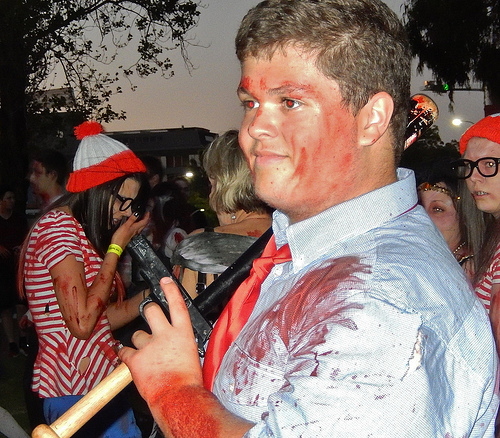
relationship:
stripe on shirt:
[38, 350, 78, 384] [19, 209, 127, 396]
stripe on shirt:
[42, 367, 66, 393] [19, 209, 127, 396]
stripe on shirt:
[40, 383, 52, 399] [19, 209, 127, 396]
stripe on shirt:
[35, 316, 61, 328] [19, 209, 127, 396]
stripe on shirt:
[24, 276, 54, 287] [19, 209, 127, 396]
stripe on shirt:
[471, 286, 493, 302] [471, 241, 497, 315]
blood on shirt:
[279, 275, 332, 321] [210, 205, 496, 435]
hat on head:
[62, 117, 143, 187] [73, 169, 135, 246]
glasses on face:
[110, 185, 138, 212] [103, 178, 137, 229]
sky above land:
[135, 74, 205, 112] [128, 123, 246, 202]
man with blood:
[111, 0, 499, 438] [293, 147, 311, 182]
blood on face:
[293, 147, 311, 182] [232, 50, 354, 212]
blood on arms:
[293, 147, 311, 182] [129, 339, 248, 435]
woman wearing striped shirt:
[18, 120, 140, 413] [12, 205, 142, 395]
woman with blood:
[18, 120, 140, 413] [56, 276, 78, 296]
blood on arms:
[56, 276, 78, 296] [39, 245, 143, 332]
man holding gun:
[163, 14, 440, 424] [128, 237, 202, 362]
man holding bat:
[111, 0, 499, 438] [58, 103, 438, 322]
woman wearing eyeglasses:
[18, 120, 140, 413] [106, 183, 135, 209]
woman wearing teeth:
[445, 110, 497, 287] [472, 188, 486, 201]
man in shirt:
[111, 0, 499, 438] [199, 186, 491, 433]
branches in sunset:
[42, 3, 179, 82] [113, 79, 197, 125]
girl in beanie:
[454, 117, 497, 322] [451, 109, 497, 142]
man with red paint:
[111, 0, 499, 438] [224, 62, 370, 212]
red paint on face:
[224, 62, 370, 212] [235, 71, 351, 203]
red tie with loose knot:
[185, 235, 302, 389] [243, 235, 292, 283]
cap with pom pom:
[61, 117, 149, 190] [74, 120, 104, 144]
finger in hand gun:
[144, 283, 168, 332] [120, 230, 223, 369]